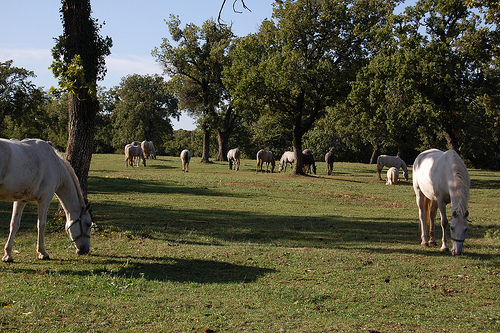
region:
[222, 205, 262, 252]
part of a shade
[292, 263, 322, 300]
part of a ground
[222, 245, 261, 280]
part of a shade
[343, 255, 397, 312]
part of a ground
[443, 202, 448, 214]
part of a an ear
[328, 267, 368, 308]
part of a ground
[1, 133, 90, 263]
a white horse grazing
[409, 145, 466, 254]
a white horse grazing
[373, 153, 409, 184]
a white horse grazing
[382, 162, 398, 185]
a white horse grazing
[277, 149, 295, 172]
a white horse grazing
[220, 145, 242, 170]
a white horse grazing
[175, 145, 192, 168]
a white horse grazing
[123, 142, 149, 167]
a white horse grazing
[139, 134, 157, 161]
a white horse grazing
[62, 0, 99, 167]
a tall tree trunk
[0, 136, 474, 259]
white horses in field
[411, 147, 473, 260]
horse grazing on grass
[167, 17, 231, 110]
green leaves on tree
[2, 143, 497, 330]
green grass on ground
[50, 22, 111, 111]
vine on tree trunk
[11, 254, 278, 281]
horse shadow on grass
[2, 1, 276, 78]
cloud low in sky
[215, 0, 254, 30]
branches with no leaves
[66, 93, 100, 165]
bark on tree trunk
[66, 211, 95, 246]
bridle on horse head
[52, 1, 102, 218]
a brown tree trunk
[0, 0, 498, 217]
trees with green leaves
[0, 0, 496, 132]
a blue sky with puffy clouds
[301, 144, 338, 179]
two black horses grazing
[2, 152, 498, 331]
a field of green grass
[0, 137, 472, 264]
a group of horses grazing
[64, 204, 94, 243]
a black horse halter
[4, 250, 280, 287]
a shadow of a standing horse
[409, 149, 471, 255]
white horse grazing in field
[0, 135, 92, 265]
white horse grazing in field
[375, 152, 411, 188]
white horse grazing in field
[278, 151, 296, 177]
white horse grazing in field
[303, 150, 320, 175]
white horse grazing in field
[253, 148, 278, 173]
white horse grazing in field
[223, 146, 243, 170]
white horse grazing in field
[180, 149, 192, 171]
white horse grazing in field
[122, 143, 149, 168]
white horse grazing in field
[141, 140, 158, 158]
white horse grazing in field